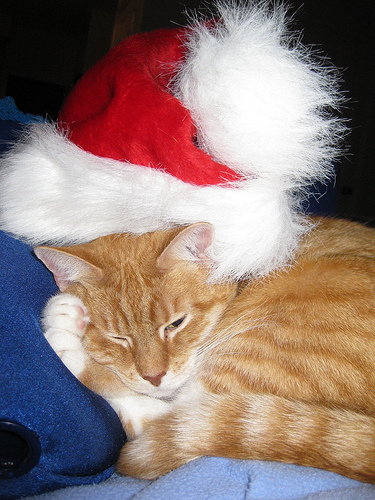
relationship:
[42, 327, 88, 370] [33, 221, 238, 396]
paw on face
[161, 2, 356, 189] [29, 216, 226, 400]
cotton near a head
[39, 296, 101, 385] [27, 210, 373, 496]
paw of a cat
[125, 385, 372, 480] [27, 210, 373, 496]
tail of a cat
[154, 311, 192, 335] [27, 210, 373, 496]
eye of a cat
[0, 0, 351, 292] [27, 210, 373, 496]
hat on a cat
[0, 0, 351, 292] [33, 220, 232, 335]
hat on head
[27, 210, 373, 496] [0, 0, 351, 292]
cat wearing hat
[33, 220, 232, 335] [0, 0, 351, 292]
head with a hat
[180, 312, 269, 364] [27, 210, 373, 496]
cat whiskers on a cat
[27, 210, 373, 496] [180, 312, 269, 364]
cat with cat whiskers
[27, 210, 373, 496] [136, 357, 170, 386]
cat with a nose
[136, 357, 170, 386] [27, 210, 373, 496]
nose on a cat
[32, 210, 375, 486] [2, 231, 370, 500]
cat on a bed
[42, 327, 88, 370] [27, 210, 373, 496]
paw on cat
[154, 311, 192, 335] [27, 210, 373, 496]
eye on cat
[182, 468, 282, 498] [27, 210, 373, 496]
blanket on cat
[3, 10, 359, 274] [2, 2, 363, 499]
hat shown in photo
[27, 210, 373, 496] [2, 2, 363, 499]
cat shown in photo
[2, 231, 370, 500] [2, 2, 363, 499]
bed shown in photo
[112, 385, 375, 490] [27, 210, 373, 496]
tail belonging to cat